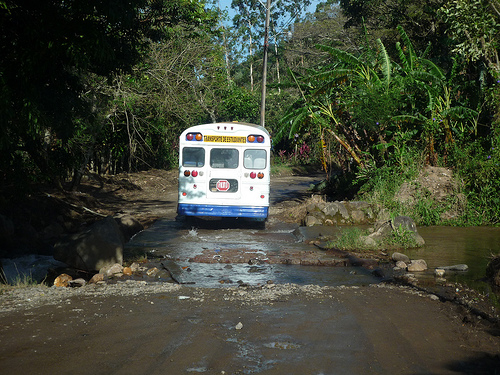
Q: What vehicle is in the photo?
A: A bus.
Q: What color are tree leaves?
A: Green.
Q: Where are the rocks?
A: On the ground.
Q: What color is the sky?
A: Blue.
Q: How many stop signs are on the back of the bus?
A: 1.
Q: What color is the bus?
A: White and blue.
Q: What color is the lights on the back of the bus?
A: Red.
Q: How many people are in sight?
A: 0.